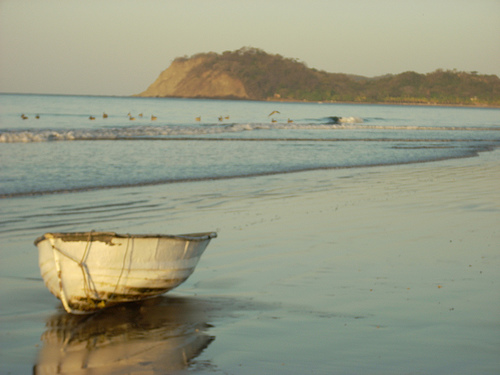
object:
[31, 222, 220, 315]
boat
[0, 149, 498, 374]
shore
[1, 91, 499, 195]
water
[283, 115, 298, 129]
birds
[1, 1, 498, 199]
background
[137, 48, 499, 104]
hills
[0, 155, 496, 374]
sand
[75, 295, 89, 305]
dirt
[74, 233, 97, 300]
ropes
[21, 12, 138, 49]
white clouds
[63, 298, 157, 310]
keel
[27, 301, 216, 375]
reflection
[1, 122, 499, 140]
wave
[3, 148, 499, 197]
coast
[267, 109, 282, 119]
seagull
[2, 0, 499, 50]
sky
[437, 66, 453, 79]
trees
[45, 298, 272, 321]
shadow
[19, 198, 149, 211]
ripples